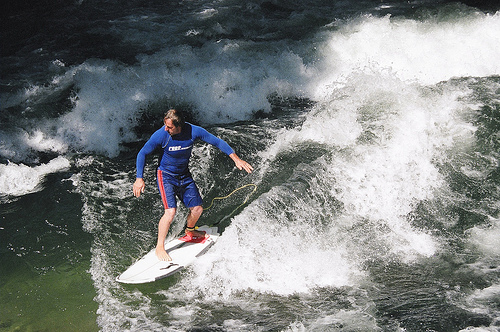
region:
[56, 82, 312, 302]
the man is surfing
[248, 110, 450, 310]
the waves are white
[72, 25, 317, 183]
the water is rolling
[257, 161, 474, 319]
the waves are splashing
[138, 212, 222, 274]
the man is bare foot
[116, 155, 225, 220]
the man is wearing shorts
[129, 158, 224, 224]
the shorts are blue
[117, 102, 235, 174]
the shirt is blue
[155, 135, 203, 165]
writing on the shirt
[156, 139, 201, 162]
the writing is white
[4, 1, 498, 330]
the choppy water the man is riding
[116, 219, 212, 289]
the surfboard the man is riding on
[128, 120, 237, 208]
the wetsuit the man is wearing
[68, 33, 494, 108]
the foamy part of the water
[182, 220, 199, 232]
the band around the man's ankle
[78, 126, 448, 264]
the wave the man is riding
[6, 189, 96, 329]
a still part of the water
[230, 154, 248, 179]
the man's left hand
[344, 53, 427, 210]
more of the foamy water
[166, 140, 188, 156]
writing on the man's shirt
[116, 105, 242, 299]
man on surf board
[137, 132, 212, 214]
wetsuit on the man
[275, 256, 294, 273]
white water wave splashing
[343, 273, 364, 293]
white water wave splashing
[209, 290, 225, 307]
white water wave splashing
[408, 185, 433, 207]
white water wave splashing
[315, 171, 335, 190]
white water wave splashing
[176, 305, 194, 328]
white water wave splashing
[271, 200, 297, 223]
white water wave splashing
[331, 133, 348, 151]
white water wave splashing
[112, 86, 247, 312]
A person standing on a board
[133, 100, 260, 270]
Man is wearing a blue suit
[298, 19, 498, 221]
Waves crashing together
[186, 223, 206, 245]
An ankle bracelet on the surfer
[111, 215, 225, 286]
The surfboard is white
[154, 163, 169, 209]
A red and orange stripe on blue shorts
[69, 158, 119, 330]
A vertical wave line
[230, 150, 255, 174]
The man's hands are bare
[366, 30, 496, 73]
The crashing waves are white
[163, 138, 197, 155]
Lettering on a man's shirt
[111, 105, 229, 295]
a man on surfboard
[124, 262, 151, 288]
a white surfboard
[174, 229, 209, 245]
a red logon the surfboard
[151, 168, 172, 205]
a red stripe on blue shorts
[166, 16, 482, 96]
a wave rolling towards the man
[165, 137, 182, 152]
white lettering on the shirt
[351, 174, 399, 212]
white sea foam on the surface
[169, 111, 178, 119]
wet brown hair on a head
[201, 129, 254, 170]
an arm reaching forward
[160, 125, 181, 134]
a nose on a face